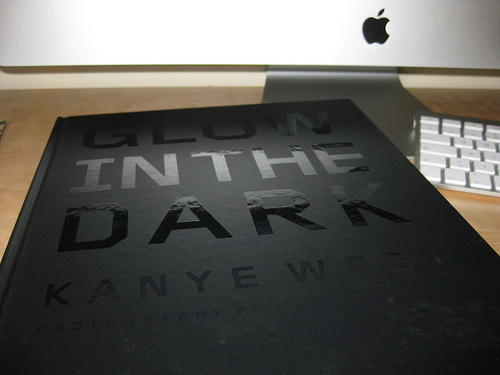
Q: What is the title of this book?
A: Glow in the dark.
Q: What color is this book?
A: Black.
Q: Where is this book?
A: On a desk.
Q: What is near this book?
A: Computer keyboard.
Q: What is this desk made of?
A: Wood.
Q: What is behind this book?
A: Computer monitor.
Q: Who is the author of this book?
A: Kanye west.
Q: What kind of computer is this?
A: Apple.